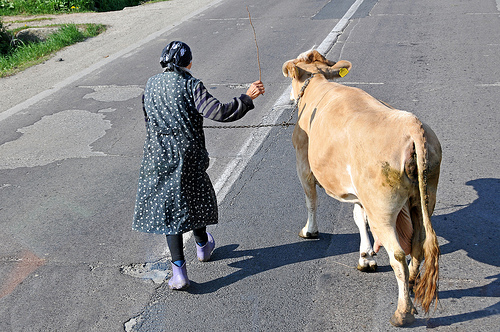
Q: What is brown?
A: Cow.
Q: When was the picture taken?
A: Daytime.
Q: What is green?
A: Grass.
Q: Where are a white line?
A: On the road.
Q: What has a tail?
A: A cow.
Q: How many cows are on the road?
A: One.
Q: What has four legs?
A: The cow.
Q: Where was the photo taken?
A: In the road.